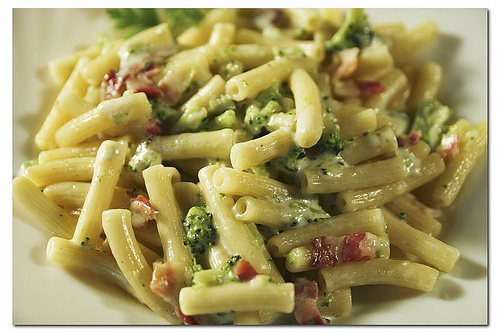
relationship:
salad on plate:
[33, 13, 463, 313] [39, 256, 458, 332]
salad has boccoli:
[33, 13, 463, 313] [182, 206, 215, 245]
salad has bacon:
[33, 13, 463, 313] [116, 66, 169, 89]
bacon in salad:
[116, 66, 169, 89] [33, 13, 463, 313]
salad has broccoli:
[33, 13, 463, 313] [166, 194, 219, 244]